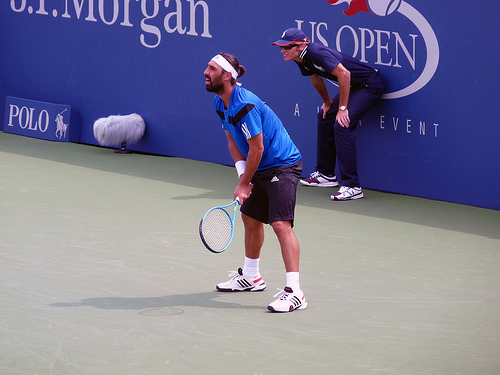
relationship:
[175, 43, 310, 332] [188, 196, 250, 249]
man holding tennis racket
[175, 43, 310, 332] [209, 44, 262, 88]
man wearing headband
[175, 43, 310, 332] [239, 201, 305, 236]
man holding knees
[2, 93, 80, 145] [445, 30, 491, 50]
ad on wall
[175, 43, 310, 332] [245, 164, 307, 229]
man in black shorts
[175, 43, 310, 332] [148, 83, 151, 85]
man playing tennis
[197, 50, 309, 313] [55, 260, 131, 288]
man on tennis court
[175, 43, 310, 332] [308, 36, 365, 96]
man in blue shirt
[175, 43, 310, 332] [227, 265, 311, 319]
man in white shoes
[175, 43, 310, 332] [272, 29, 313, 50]
man in hat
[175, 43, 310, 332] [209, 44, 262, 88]
man in headband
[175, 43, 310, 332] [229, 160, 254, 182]
man in wristband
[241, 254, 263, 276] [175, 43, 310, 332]
sock of man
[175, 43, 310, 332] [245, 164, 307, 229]
man in shorts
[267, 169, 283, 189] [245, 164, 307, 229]
emblem on black shorts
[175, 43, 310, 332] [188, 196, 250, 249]
man has tennis racket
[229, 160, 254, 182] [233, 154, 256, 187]
wristband on arm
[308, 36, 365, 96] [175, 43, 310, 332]
blue shirt of man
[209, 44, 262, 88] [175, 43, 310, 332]
headband on man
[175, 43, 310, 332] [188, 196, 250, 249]
man carrying tennis racket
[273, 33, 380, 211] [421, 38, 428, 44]
boy for balls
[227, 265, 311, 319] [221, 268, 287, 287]
white shoes on right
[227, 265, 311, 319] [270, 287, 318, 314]
white shoes on left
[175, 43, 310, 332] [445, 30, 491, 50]
man on wall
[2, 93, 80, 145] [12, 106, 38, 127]
ad says polo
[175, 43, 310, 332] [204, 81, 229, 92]
man has beard